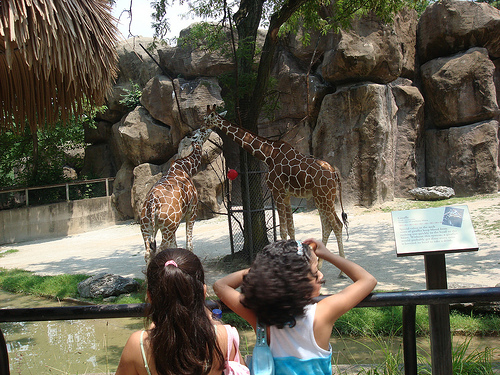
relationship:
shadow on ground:
[25, 243, 146, 276] [1, 186, 500, 334]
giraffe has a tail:
[204, 105, 350, 279] [334, 172, 352, 237]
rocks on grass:
[82, 0, 500, 222] [380, 198, 475, 210]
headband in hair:
[293, 238, 305, 260] [239, 240, 313, 326]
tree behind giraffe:
[216, 0, 431, 262] [204, 105, 350, 279]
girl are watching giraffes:
[118, 238, 378, 374] [140, 102, 354, 281]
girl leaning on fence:
[210, 237, 372, 375] [1, 284, 500, 375]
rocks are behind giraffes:
[102, 0, 498, 221] [140, 102, 354, 281]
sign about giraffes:
[390, 204, 480, 255] [140, 102, 354, 281]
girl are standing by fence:
[118, 238, 378, 374] [1, 284, 500, 375]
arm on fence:
[212, 264, 264, 326] [1, 284, 500, 375]